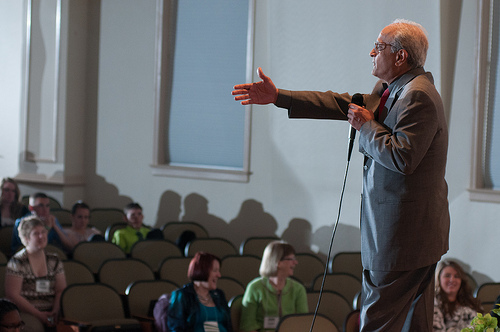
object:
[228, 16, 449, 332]
man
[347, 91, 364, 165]
mic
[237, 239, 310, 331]
women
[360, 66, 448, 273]
coat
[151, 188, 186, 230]
shadows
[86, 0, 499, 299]
wall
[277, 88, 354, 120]
arm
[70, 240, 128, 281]
seats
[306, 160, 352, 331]
cord